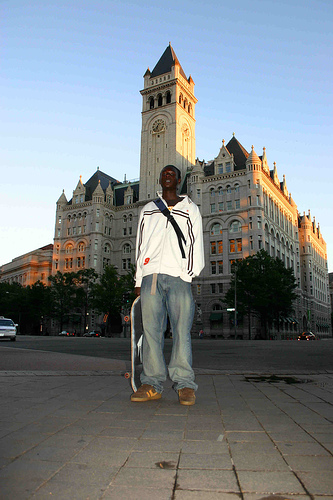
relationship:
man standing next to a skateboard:
[124, 160, 216, 402] [121, 284, 146, 392]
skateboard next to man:
[121, 284, 146, 392] [124, 160, 216, 402]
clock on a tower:
[148, 115, 171, 135] [133, 41, 191, 194]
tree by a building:
[225, 247, 309, 342] [190, 128, 330, 339]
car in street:
[0, 312, 21, 345] [2, 340, 114, 479]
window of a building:
[217, 160, 231, 172] [190, 128, 330, 339]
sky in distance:
[6, 12, 139, 140] [134, 23, 192, 42]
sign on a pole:
[224, 307, 235, 314] [233, 265, 240, 332]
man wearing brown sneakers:
[124, 160, 216, 402] [128, 377, 198, 406]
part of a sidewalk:
[40, 403, 72, 429] [24, 396, 302, 497]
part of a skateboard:
[135, 315, 141, 329] [121, 284, 146, 392]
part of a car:
[10, 327, 14, 335] [0, 312, 21, 345]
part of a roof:
[237, 150, 243, 156] [228, 136, 251, 169]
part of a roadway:
[291, 347, 309, 358] [263, 340, 333, 382]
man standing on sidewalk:
[124, 160, 216, 402] [24, 396, 302, 497]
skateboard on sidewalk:
[121, 284, 146, 392] [24, 396, 302, 497]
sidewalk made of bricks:
[24, 396, 302, 497] [147, 423, 233, 459]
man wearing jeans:
[124, 160, 216, 402] [131, 271, 204, 396]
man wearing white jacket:
[124, 160, 216, 402] [137, 193, 207, 280]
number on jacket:
[143, 258, 150, 267] [137, 193, 207, 280]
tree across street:
[225, 247, 309, 342] [2, 340, 114, 479]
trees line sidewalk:
[3, 269, 131, 331] [35, 330, 109, 349]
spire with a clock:
[138, 38, 192, 84] [148, 115, 171, 135]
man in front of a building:
[124, 160, 216, 402] [190, 128, 330, 339]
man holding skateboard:
[124, 160, 216, 402] [121, 284, 146, 392]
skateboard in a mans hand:
[121, 284, 146, 392] [132, 282, 142, 299]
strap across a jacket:
[149, 195, 189, 261] [137, 193, 207, 280]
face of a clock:
[152, 119, 164, 131] [148, 115, 171, 135]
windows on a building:
[206, 182, 250, 216] [190, 128, 330, 339]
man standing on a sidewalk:
[124, 160, 216, 402] [24, 396, 302, 497]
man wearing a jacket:
[124, 160, 216, 402] [137, 193, 207, 280]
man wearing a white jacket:
[124, 160, 216, 402] [137, 193, 207, 280]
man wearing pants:
[124, 160, 216, 402] [131, 271, 204, 396]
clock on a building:
[148, 115, 171, 135] [190, 128, 330, 339]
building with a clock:
[190, 128, 330, 339] [148, 115, 171, 135]